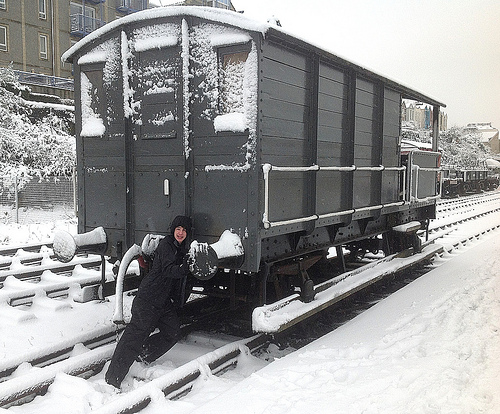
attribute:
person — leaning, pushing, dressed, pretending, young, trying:
[81, 208, 202, 395]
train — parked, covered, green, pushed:
[65, 14, 441, 276]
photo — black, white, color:
[4, 2, 497, 413]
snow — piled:
[21, 374, 97, 413]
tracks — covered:
[9, 324, 229, 413]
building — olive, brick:
[1, 1, 147, 105]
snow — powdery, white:
[167, 5, 275, 34]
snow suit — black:
[107, 239, 191, 396]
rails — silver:
[255, 162, 445, 174]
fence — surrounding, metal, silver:
[4, 174, 78, 225]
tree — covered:
[2, 68, 67, 164]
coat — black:
[120, 244, 190, 315]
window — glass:
[215, 49, 254, 111]